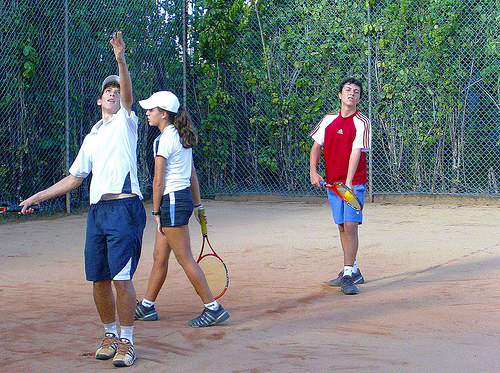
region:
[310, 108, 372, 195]
boy has on red and white shirt.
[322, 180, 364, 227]
boy has on blue shorts.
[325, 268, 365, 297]
boy is wearing blue shoes.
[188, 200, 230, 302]
girl is holding red tennis racket.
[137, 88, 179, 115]
girl has white cap on.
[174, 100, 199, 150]
girl has a ponytail.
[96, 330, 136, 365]
boy has on tan shoes.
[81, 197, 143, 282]
boy is wearing navy and white shorts.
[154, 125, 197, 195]
girl is wearing white shirt.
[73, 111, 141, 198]
boy is wearing white shirt.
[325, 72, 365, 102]
head of a person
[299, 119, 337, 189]
arm of a person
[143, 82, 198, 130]
head of a person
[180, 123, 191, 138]
hair of a person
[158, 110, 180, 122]
ear of a person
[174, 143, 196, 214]
back of a person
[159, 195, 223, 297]
leg of a person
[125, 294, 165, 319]
feet of a person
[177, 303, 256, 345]
feet of a person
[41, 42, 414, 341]
Tennis players at the court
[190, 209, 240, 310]
A tennis racket in the photo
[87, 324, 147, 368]
Shoes in the photo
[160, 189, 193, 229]
A short in the photo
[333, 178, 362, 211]
A tennis racket in the hands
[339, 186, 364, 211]
A tennis ball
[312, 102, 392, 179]
A red and white jersey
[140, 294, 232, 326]
Black and gray shoes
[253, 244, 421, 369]
A tennis playing surface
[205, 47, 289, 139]
A wire mesh fence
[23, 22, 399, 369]
Three people about to play tennis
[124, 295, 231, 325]
Black and silver shoes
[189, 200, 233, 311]
A red tennis racket with a yellow handle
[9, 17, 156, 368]
A boy with his hand in the air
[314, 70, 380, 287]
A boy holding a tennis racket and a tennis ball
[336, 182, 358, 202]
A tennis ball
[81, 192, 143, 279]
Blue and white sport shorts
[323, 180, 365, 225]
Light blue sports shorts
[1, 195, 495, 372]
A red dirt tennis court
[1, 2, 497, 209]
A grey chainlink fence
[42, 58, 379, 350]
people on the court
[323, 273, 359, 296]
shoes on the feet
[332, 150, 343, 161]
the shirt is red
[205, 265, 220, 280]
netting on the racket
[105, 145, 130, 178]
the shirt is red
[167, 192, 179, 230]
stripe on the shorts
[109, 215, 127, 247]
the shorts are blue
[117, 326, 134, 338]
sock on the leg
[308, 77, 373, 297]
young man holding a tennis racket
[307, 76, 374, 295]
young man wearing red shirt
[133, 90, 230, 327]
girl holding a tennis racket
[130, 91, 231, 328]
girl wearing a cap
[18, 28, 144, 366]
young man looking up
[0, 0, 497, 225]
metal fence behind of players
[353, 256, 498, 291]
man's shadow on the ground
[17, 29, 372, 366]
three people on the tennis court